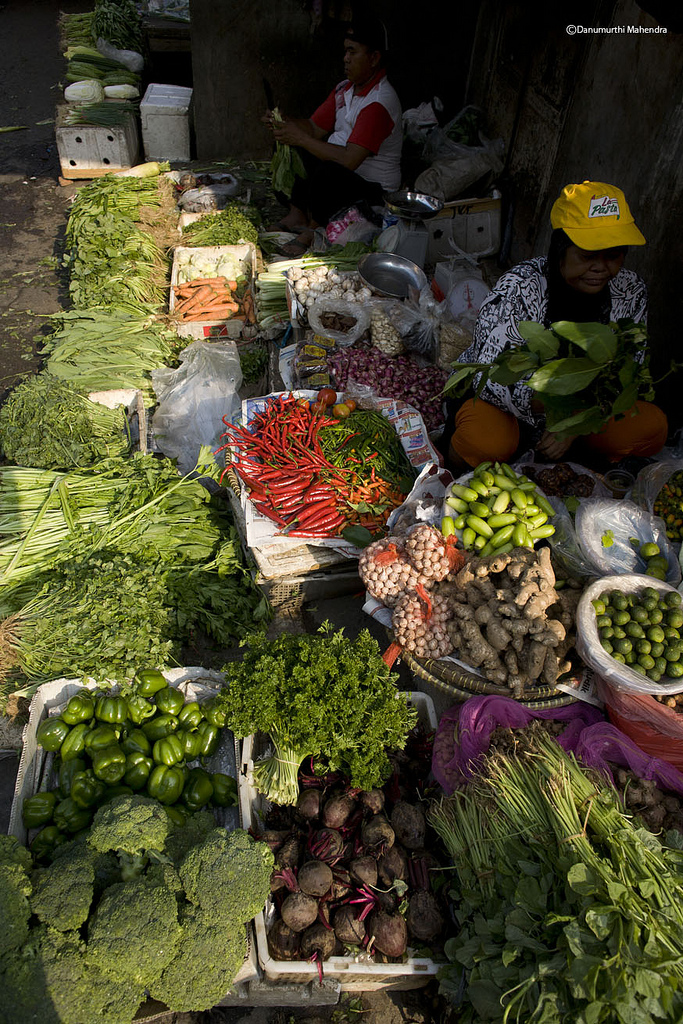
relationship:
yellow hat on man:
[552, 177, 649, 249] [258, 2, 403, 259]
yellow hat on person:
[552, 177, 649, 249] [455, 173, 672, 478]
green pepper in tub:
[90, 745, 126, 783] [13, 667, 253, 998]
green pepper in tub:
[33, 719, 69, 752] [13, 667, 253, 998]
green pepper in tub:
[59, 692, 96, 720] [13, 667, 253, 998]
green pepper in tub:
[96, 690, 127, 720] [13, 667, 253, 998]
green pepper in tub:
[176, 699, 202, 725] [13, 667, 253, 998]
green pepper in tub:
[185, 769, 212, 809] [13, 667, 253, 998]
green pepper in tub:
[210, 767, 235, 808] [13, 667, 253, 998]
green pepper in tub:
[146, 764, 186, 804] [13, 667, 253, 998]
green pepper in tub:
[23, 788, 58, 823] [13, 667, 253, 998]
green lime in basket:
[645, 594, 655, 610] [574, 569, 681, 716]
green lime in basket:
[649, 623, 665, 641] [574, 569, 681, 716]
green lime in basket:
[636, 651, 655, 668] [574, 569, 681, 716]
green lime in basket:
[616, 635, 629, 650] [574, 569, 681, 716]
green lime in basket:
[614, 608, 629, 625] [574, 569, 681, 716]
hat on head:
[346, 15, 388, 55] [333, 20, 383, 80]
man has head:
[279, 15, 410, 262] [333, 20, 383, 80]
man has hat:
[279, 15, 410, 262] [346, 15, 388, 55]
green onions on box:
[61, 100, 129, 127] [59, 96, 138, 181]